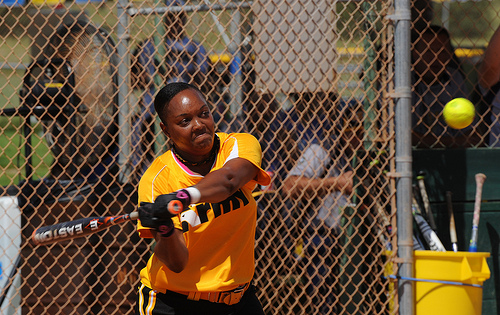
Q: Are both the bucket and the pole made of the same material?
A: No, the bucket is made of plastic and the pole is made of metal.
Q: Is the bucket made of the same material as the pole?
A: No, the bucket is made of plastic and the pole is made of metal.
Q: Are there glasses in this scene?
A: No, there are no glasses.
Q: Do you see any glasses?
A: No, there are no glasses.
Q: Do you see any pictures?
A: No, there are no pictures.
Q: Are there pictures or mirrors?
A: No, there are no pictures or mirrors.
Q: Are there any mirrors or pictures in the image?
A: No, there are no pictures or mirrors.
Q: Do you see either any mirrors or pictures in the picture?
A: No, there are no pictures or mirrors.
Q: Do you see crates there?
A: No, there are no crates.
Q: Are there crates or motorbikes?
A: No, there are no crates or motorbikes.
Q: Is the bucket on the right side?
A: Yes, the bucket is on the right of the image.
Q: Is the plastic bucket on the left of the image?
A: No, the bucket is on the right of the image.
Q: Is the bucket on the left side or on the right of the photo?
A: The bucket is on the right of the image.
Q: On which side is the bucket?
A: The bucket is on the right of the image.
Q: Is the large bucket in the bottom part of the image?
A: Yes, the bucket is in the bottom of the image.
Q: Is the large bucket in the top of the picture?
A: No, the bucket is in the bottom of the image.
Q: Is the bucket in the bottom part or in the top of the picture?
A: The bucket is in the bottom of the image.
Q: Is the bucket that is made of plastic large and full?
A: Yes, the bucket is large and full.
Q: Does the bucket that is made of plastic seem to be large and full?
A: Yes, the bucket is large and full.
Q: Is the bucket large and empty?
A: No, the bucket is large but full.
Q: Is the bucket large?
A: Yes, the bucket is large.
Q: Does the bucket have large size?
A: Yes, the bucket is large.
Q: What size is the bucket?
A: The bucket is large.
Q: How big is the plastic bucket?
A: The bucket is large.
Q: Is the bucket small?
A: No, the bucket is large.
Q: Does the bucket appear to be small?
A: No, the bucket is large.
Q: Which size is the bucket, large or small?
A: The bucket is large.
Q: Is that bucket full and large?
A: Yes, the bucket is full and large.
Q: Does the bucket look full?
A: Yes, the bucket is full.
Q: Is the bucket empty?
A: No, the bucket is full.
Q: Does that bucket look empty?
A: No, the bucket is full.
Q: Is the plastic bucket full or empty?
A: The bucket is full.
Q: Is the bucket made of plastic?
A: Yes, the bucket is made of plastic.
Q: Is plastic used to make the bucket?
A: Yes, the bucket is made of plastic.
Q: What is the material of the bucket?
A: The bucket is made of plastic.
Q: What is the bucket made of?
A: The bucket is made of plastic.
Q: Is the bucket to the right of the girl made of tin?
A: No, the bucket is made of plastic.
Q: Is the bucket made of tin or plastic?
A: The bucket is made of plastic.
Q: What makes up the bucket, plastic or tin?
A: The bucket is made of plastic.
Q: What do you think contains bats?
A: The bucket contains bats.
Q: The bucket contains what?
A: The bucket contains bats.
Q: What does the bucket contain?
A: The bucket contains bats.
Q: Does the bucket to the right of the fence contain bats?
A: Yes, the bucket contains bats.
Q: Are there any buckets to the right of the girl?
A: Yes, there is a bucket to the right of the girl.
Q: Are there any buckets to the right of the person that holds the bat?
A: Yes, there is a bucket to the right of the girl.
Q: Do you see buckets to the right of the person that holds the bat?
A: Yes, there is a bucket to the right of the girl.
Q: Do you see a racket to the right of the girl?
A: No, there is a bucket to the right of the girl.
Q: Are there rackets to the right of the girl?
A: No, there is a bucket to the right of the girl.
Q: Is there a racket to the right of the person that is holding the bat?
A: No, there is a bucket to the right of the girl.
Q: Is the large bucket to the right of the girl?
A: Yes, the bucket is to the right of the girl.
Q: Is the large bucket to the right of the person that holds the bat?
A: Yes, the bucket is to the right of the girl.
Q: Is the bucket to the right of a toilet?
A: No, the bucket is to the right of the girl.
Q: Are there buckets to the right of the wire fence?
A: Yes, there is a bucket to the right of the fence.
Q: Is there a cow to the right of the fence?
A: No, there is a bucket to the right of the fence.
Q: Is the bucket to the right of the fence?
A: Yes, the bucket is to the right of the fence.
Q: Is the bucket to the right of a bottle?
A: No, the bucket is to the right of the fence.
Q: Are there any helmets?
A: No, there are no helmets.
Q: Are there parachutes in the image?
A: No, there are no parachutes.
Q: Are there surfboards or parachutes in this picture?
A: No, there are no parachutes or surfboards.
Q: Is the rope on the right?
A: Yes, the rope is on the right of the image.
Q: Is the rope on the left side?
A: No, the rope is on the right of the image.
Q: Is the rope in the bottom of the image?
A: Yes, the rope is in the bottom of the image.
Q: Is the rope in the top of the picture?
A: No, the rope is in the bottom of the image.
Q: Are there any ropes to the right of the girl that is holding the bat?
A: Yes, there is a rope to the right of the girl.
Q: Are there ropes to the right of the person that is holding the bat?
A: Yes, there is a rope to the right of the girl.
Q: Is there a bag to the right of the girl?
A: No, there is a rope to the right of the girl.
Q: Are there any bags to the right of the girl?
A: No, there is a rope to the right of the girl.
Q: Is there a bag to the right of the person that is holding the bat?
A: No, there is a rope to the right of the girl.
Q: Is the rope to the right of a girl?
A: Yes, the rope is to the right of a girl.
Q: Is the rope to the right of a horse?
A: No, the rope is to the right of a girl.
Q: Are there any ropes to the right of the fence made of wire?
A: Yes, there is a rope to the right of the fence.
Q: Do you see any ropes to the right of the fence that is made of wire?
A: Yes, there is a rope to the right of the fence.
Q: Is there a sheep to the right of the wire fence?
A: No, there is a rope to the right of the fence.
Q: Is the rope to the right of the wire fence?
A: Yes, the rope is to the right of the fence.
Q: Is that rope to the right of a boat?
A: No, the rope is to the right of the fence.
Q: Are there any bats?
A: Yes, there is a bat.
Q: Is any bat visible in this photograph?
A: Yes, there is a bat.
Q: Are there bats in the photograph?
A: Yes, there is a bat.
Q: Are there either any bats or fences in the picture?
A: Yes, there is a bat.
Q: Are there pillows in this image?
A: No, there are no pillows.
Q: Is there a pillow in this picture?
A: No, there are no pillows.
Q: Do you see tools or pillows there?
A: No, there are no pillows or tools.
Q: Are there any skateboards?
A: No, there are no skateboards.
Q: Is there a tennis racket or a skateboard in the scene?
A: No, there are no skateboards or rackets.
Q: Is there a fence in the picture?
A: Yes, there is a fence.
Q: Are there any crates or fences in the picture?
A: Yes, there is a fence.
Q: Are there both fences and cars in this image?
A: No, there is a fence but no cars.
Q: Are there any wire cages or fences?
A: Yes, there is a wire fence.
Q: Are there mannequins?
A: No, there are no mannequins.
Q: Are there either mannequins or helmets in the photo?
A: No, there are no mannequins or helmets.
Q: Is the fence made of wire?
A: Yes, the fence is made of wire.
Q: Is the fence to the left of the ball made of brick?
A: No, the fence is made of wire.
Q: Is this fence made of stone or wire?
A: The fence is made of wire.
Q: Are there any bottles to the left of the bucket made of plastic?
A: No, there is a fence to the left of the bucket.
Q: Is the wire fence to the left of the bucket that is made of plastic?
A: Yes, the fence is to the left of the bucket.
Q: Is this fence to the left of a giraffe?
A: No, the fence is to the left of the bucket.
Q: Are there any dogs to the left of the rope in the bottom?
A: No, there is a fence to the left of the rope.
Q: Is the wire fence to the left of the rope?
A: Yes, the fence is to the left of the rope.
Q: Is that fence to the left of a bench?
A: No, the fence is to the left of the rope.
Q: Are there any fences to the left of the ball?
A: Yes, there is a fence to the left of the ball.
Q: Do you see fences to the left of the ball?
A: Yes, there is a fence to the left of the ball.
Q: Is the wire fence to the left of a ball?
A: Yes, the fence is to the left of a ball.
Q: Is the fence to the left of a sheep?
A: No, the fence is to the left of a ball.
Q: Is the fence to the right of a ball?
A: No, the fence is to the left of a ball.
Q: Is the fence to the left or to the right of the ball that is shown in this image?
A: The fence is to the left of the ball.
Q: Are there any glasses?
A: No, there are no glasses.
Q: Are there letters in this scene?
A: Yes, there are letters.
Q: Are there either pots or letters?
A: Yes, there are letters.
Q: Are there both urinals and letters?
A: No, there are letters but no urinals.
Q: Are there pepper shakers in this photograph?
A: No, there are no pepper shakers.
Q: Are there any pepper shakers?
A: No, there are no pepper shakers.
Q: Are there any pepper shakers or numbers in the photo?
A: No, there are no pepper shakers or numbers.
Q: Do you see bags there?
A: No, there are no bags.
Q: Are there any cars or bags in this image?
A: No, there are no bags or cars.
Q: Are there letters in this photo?
A: Yes, there are letters.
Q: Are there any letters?
A: Yes, there are letters.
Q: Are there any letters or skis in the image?
A: Yes, there are letters.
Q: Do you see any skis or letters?
A: Yes, there are letters.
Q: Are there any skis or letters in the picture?
A: Yes, there are letters.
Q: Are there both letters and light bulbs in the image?
A: No, there are letters but no light bulbs.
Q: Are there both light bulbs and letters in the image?
A: No, there are letters but no light bulbs.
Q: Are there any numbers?
A: No, there are no numbers.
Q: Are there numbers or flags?
A: No, there are no numbers or flags.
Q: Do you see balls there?
A: Yes, there is a ball.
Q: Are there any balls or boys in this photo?
A: Yes, there is a ball.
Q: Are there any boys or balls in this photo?
A: Yes, there is a ball.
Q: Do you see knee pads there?
A: No, there are no knee pads.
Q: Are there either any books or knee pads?
A: No, there are no knee pads or books.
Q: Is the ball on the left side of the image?
A: No, the ball is on the right of the image.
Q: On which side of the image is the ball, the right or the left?
A: The ball is on the right of the image.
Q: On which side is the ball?
A: The ball is on the right of the image.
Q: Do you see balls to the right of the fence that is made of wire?
A: Yes, there is a ball to the right of the fence.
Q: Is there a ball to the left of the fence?
A: No, the ball is to the right of the fence.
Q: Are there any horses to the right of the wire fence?
A: No, there is a ball to the right of the fence.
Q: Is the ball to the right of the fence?
A: Yes, the ball is to the right of the fence.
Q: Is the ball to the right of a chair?
A: No, the ball is to the right of the fence.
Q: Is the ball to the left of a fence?
A: No, the ball is to the right of a fence.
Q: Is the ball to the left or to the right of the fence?
A: The ball is to the right of the fence.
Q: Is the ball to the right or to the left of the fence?
A: The ball is to the right of the fence.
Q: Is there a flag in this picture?
A: No, there are no flags.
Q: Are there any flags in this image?
A: No, there are no flags.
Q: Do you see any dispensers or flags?
A: No, there are no flags or dispensers.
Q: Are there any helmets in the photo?
A: No, there are no helmets.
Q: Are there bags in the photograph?
A: No, there are no bags.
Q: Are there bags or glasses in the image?
A: No, there are no bags or glasses.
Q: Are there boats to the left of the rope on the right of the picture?
A: No, there is a girl to the left of the rope.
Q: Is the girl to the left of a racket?
A: No, the girl is to the left of the rope.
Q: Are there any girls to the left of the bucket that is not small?
A: Yes, there is a girl to the left of the bucket.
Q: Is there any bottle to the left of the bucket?
A: No, there is a girl to the left of the bucket.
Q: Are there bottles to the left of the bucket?
A: No, there is a girl to the left of the bucket.